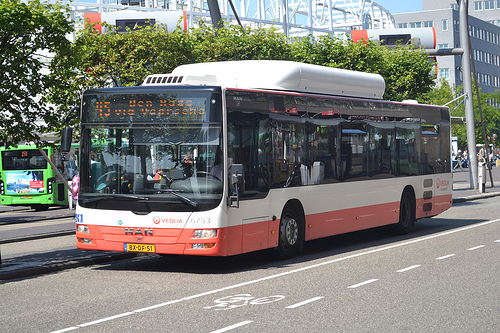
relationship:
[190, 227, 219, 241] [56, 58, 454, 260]
light built into bus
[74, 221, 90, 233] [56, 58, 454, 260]
light built into bus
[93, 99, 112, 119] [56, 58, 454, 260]
number 45 lit up on bus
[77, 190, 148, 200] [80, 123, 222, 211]
wiper mounted on windshield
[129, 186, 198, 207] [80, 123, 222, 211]
wiper mounted on windshield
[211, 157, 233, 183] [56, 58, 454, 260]
driver sitting inside bus